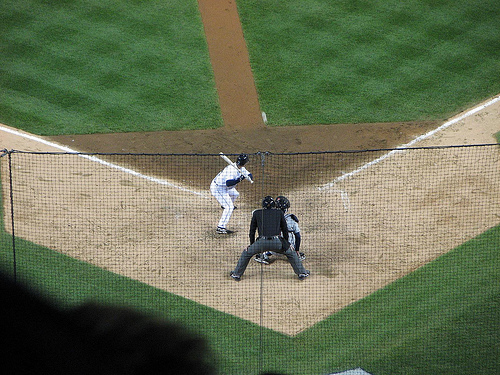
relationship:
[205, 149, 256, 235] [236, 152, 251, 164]
baseball player wearing helmet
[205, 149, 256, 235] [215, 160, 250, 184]
baseball player wearing shirt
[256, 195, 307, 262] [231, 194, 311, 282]
catcher in front of umpire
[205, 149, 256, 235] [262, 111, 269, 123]
baseball player watching baseball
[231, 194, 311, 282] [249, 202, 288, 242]
umpire wearing shirt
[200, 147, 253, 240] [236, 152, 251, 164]
player wearing helmet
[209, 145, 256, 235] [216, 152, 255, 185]
baseball player holding bat